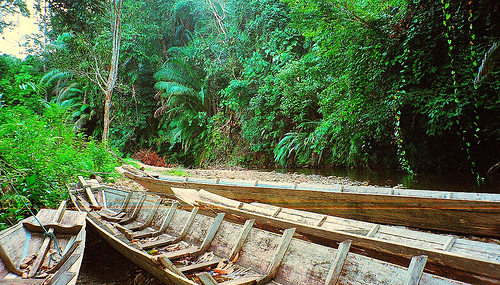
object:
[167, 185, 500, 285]
boats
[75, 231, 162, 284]
ground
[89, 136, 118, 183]
plants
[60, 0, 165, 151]
trees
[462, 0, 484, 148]
vines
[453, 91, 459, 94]
leave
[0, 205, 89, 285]
boat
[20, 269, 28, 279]
debsris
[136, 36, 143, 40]
leaves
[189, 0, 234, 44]
features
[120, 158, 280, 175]
path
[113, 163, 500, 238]
boat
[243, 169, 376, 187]
shore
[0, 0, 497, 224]
forest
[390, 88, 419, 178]
ivy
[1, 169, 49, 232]
rope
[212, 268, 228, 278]
leaves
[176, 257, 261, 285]
floor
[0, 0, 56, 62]
sky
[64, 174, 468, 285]
boat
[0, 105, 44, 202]
vegetation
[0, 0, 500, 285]
picture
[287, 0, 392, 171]
brush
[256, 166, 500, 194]
water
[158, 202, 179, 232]
slats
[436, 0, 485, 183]
vine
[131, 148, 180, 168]
patch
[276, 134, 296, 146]
ferns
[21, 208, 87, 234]
foot rest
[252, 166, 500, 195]
river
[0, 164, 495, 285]
field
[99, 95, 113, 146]
trunk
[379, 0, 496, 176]
tree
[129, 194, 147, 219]
pieces